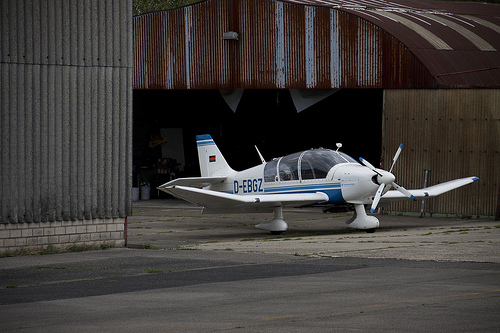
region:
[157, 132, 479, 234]
A small white and blue plane.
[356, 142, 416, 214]
Four blade white and blue propeller.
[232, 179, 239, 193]
Blue letter D on the side of a plane.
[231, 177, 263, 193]
D-E8GZ on the side of a plane.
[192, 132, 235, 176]
A white and blue tail end of a plane.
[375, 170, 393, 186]
White nose of a plane.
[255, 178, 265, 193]
A blue Z.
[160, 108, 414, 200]
white and blue plane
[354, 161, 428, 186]
white and blue propeller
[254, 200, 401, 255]
white landing gear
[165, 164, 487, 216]
white and blue wings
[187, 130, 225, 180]
red white and blue tail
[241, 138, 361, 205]
three windows on cockpit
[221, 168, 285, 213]
blue letters on plane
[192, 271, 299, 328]
concrete is dark grey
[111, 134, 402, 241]
plane is parked near hangar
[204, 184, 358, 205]
blue stripe on plane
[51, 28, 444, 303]
this is a garage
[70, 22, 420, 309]
this is a hanger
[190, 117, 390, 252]
this is an airplane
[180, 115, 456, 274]
the airplane is small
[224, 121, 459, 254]
the plane is blue and white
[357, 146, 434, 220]
the plane has a propeller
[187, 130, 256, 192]
the tail is blue and white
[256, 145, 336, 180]
the cockpit has a window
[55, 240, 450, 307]
this is an airport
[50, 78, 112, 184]
the hanger is sheet metal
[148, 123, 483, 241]
a plane on ground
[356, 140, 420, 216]
propeller of the plane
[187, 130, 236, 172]
vertical stabilizer of the plane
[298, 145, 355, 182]
cockpit of the plane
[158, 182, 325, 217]
wing of the plane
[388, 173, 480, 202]
wing of the plane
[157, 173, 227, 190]
horizontal stabilizer of the plane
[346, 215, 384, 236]
landing gear of the plane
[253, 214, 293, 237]
landing gear of the plane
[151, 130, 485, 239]
white and blue plane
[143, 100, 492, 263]
this is a small plane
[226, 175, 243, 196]
a letter on the plane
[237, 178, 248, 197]
a letter on the plane